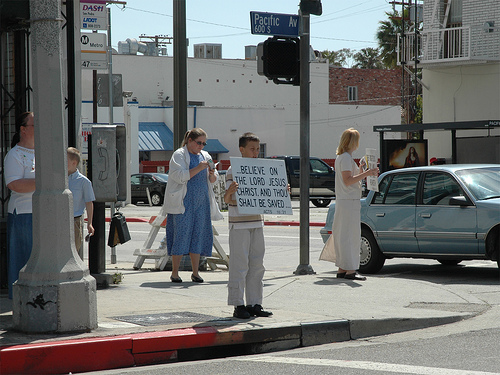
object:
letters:
[255, 13, 298, 33]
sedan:
[320, 164, 500, 275]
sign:
[250, 11, 299, 37]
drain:
[177, 338, 298, 362]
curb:
[0, 318, 350, 375]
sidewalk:
[0, 201, 500, 375]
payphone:
[88, 124, 128, 291]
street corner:
[299, 273, 464, 349]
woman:
[319, 128, 380, 281]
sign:
[359, 147, 379, 192]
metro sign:
[80, 3, 108, 70]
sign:
[229, 156, 293, 215]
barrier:
[132, 208, 230, 269]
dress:
[319, 152, 362, 271]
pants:
[227, 225, 266, 306]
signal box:
[256, 35, 301, 86]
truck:
[266, 156, 335, 208]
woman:
[158, 128, 225, 283]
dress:
[158, 145, 225, 257]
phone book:
[107, 212, 131, 247]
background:
[130, 155, 500, 273]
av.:
[261, 55, 265, 59]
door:
[416, 170, 479, 253]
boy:
[224, 132, 293, 319]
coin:
[97, 137, 108, 148]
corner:
[445, 323, 500, 374]